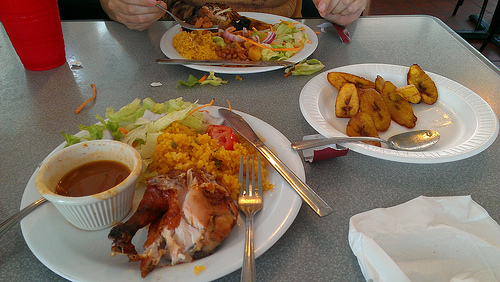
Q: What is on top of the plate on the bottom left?
A: A fork and knife.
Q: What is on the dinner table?
A: Napkins.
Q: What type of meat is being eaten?
A: Chicken.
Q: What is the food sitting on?
A: Plate.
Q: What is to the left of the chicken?
A: Barbecue sauce.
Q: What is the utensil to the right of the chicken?
A: Fork.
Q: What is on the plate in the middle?
A: Fried plantains.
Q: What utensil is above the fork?
A: Knife.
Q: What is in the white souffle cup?
A: Dipping sauce.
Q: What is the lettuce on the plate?
A: Salad.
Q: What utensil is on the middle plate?
A: Spoon.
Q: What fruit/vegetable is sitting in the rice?
A: Tomato.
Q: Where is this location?
A: Restaurant.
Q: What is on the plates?
A: Food.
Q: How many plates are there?
A: Three.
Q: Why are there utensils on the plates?
A: To eat with.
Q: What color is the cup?
A: Red.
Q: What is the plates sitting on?
A: Table.